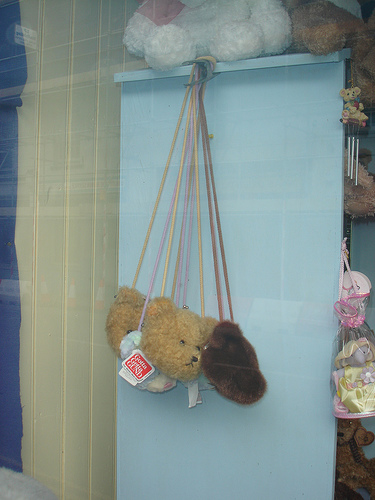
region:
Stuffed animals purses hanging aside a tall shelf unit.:
[105, 52, 267, 405]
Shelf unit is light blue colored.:
[112, 56, 343, 493]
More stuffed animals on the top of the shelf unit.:
[110, 0, 371, 47]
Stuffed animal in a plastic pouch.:
[327, 288, 369, 420]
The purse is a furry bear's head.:
[142, 296, 209, 376]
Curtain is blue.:
[0, 28, 25, 465]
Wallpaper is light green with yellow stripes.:
[28, 6, 103, 484]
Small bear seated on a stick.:
[337, 84, 367, 183]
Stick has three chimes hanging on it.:
[338, 116, 366, 184]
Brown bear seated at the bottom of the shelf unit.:
[336, 420, 373, 499]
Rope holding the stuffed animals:
[127, 75, 229, 289]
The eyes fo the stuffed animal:
[178, 333, 205, 349]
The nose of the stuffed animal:
[189, 353, 198, 361]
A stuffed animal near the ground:
[336, 415, 374, 487]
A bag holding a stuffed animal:
[336, 285, 373, 410]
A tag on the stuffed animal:
[120, 352, 151, 384]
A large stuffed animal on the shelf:
[129, 0, 285, 68]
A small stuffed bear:
[338, 86, 365, 119]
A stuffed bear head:
[140, 301, 211, 377]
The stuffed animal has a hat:
[335, 337, 369, 359]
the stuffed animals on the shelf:
[105, 0, 374, 499]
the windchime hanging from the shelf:
[339, 60, 368, 186]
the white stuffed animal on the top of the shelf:
[122, 0, 291, 72]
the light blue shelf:
[112, 46, 373, 497]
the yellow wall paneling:
[15, 0, 150, 499]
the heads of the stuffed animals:
[105, 284, 267, 405]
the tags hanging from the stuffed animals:
[118, 349, 153, 385]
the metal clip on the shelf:
[181, 58, 220, 86]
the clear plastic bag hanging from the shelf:
[330, 291, 373, 418]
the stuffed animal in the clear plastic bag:
[332, 337, 374, 412]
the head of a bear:
[142, 290, 214, 383]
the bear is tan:
[146, 293, 203, 376]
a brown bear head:
[197, 320, 269, 406]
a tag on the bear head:
[119, 348, 151, 383]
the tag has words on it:
[126, 352, 150, 380]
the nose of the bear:
[190, 352, 197, 365]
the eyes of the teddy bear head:
[178, 332, 203, 350]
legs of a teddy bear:
[140, 28, 263, 62]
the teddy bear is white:
[99, 2, 298, 54]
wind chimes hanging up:
[339, 84, 367, 187]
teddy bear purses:
[69, 86, 284, 375]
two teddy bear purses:
[35, 185, 370, 464]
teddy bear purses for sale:
[73, 233, 371, 479]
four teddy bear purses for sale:
[104, 268, 365, 437]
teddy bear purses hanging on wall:
[101, 35, 315, 412]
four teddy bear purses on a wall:
[96, 28, 273, 432]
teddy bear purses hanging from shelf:
[79, 38, 359, 451]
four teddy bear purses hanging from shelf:
[37, 48, 364, 408]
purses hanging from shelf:
[62, 27, 345, 427]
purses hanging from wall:
[86, 43, 342, 427]